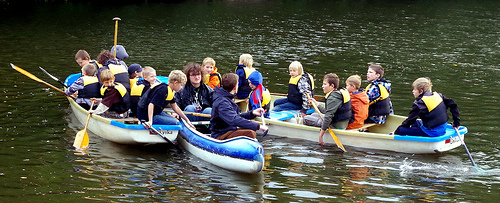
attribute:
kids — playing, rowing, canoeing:
[63, 43, 424, 132]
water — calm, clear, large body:
[11, 9, 425, 200]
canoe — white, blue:
[54, 61, 170, 147]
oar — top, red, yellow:
[69, 126, 106, 154]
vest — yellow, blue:
[418, 90, 443, 131]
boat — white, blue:
[200, 64, 463, 156]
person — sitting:
[211, 72, 257, 138]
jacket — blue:
[214, 77, 233, 129]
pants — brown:
[208, 123, 252, 141]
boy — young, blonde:
[137, 72, 201, 119]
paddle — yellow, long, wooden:
[67, 97, 103, 163]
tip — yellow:
[73, 125, 92, 150]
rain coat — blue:
[211, 80, 238, 126]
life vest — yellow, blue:
[411, 97, 455, 138]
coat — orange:
[350, 85, 365, 124]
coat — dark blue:
[215, 92, 242, 125]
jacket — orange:
[340, 84, 373, 131]